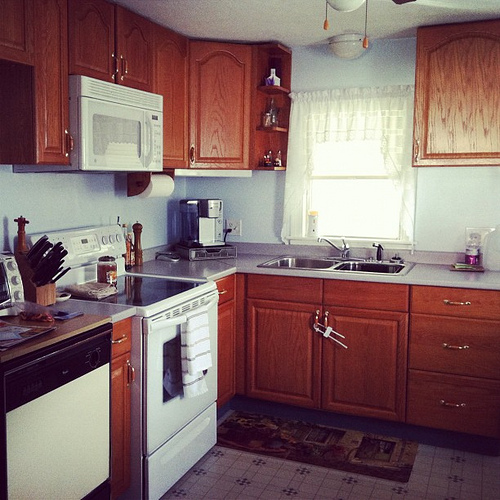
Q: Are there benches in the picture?
A: No, there are no benches.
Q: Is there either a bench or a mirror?
A: No, there are no benches or mirrors.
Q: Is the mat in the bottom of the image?
A: Yes, the mat is in the bottom of the image.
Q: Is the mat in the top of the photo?
A: No, the mat is in the bottom of the image.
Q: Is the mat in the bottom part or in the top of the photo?
A: The mat is in the bottom of the image.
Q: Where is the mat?
A: The mat is on the floor.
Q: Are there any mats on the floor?
A: Yes, there is a mat on the floor.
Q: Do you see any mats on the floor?
A: Yes, there is a mat on the floor.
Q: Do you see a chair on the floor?
A: No, there is a mat on the floor.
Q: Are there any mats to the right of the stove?
A: Yes, there is a mat to the right of the stove.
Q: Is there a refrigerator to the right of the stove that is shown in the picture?
A: No, there is a mat to the right of the stove.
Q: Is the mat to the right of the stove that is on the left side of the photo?
A: Yes, the mat is to the right of the stove.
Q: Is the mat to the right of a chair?
A: No, the mat is to the right of the stove.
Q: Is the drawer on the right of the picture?
A: Yes, the drawer is on the right of the image.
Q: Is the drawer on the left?
A: No, the drawer is on the right of the image.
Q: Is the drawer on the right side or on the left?
A: The drawer is on the right of the image.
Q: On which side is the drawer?
A: The drawer is on the right of the image.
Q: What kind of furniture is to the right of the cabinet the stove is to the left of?
A: The piece of furniture is a drawer.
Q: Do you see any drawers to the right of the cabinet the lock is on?
A: Yes, there is a drawer to the right of the cabinet.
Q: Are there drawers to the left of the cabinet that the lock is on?
A: No, the drawer is to the right of the cabinet.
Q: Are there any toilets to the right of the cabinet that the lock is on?
A: No, there is a drawer to the right of the cabinet.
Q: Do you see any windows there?
A: Yes, there are windows.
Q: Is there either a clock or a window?
A: Yes, there are windows.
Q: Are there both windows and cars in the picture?
A: No, there are windows but no cars.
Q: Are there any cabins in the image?
A: No, there are no cabins.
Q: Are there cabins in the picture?
A: No, there are no cabins.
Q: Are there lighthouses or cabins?
A: No, there are no cabins or lighthouses.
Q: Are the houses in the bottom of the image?
A: Yes, the houses are in the bottom of the image.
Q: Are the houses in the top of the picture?
A: No, the houses are in the bottom of the image.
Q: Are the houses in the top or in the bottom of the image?
A: The houses are in the bottom of the image.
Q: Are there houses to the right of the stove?
A: Yes, there are houses to the right of the stove.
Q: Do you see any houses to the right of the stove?
A: Yes, there are houses to the right of the stove.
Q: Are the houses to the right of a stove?
A: Yes, the houses are to the right of a stove.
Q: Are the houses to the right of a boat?
A: No, the houses are to the right of a stove.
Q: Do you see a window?
A: Yes, there are windows.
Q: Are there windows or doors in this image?
A: Yes, there are windows.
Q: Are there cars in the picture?
A: No, there are no cars.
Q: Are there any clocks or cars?
A: No, there are no cars or clocks.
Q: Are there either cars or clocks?
A: No, there are no cars or clocks.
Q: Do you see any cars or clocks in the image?
A: No, there are no cars or clocks.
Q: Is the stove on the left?
A: Yes, the stove is on the left of the image.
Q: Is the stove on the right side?
A: No, the stove is on the left of the image.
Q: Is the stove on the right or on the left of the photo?
A: The stove is on the left of the image.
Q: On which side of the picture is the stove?
A: The stove is on the left of the image.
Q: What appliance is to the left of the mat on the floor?
A: The appliance is a stove.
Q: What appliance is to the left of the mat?
A: The appliance is a stove.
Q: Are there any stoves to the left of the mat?
A: Yes, there is a stove to the left of the mat.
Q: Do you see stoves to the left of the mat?
A: Yes, there is a stove to the left of the mat.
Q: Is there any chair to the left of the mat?
A: No, there is a stove to the left of the mat.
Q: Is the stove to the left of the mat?
A: Yes, the stove is to the left of the mat.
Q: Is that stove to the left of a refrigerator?
A: No, the stove is to the left of the mat.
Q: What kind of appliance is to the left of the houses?
A: The appliance is a stove.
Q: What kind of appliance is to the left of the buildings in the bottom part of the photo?
A: The appliance is a stove.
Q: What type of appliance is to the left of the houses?
A: The appliance is a stove.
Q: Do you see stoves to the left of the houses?
A: Yes, there is a stove to the left of the houses.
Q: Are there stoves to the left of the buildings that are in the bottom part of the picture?
A: Yes, there is a stove to the left of the houses.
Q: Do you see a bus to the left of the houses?
A: No, there is a stove to the left of the houses.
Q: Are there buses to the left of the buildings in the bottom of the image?
A: No, there is a stove to the left of the houses.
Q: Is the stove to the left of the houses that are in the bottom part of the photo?
A: Yes, the stove is to the left of the houses.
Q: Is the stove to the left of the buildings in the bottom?
A: Yes, the stove is to the left of the houses.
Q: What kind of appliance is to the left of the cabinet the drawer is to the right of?
A: The appliance is a stove.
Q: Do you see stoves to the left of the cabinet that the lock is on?
A: Yes, there is a stove to the left of the cabinet.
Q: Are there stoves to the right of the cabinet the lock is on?
A: No, the stove is to the left of the cabinet.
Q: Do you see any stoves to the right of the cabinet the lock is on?
A: No, the stove is to the left of the cabinet.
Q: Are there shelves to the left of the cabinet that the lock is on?
A: No, there is a stove to the left of the cabinet.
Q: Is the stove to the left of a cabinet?
A: Yes, the stove is to the left of a cabinet.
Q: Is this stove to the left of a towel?
A: No, the stove is to the left of a cabinet.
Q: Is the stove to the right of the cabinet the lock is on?
A: No, the stove is to the left of the cabinet.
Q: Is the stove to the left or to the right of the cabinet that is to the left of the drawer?
A: The stove is to the left of the cabinet.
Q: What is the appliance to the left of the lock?
A: The appliance is a stove.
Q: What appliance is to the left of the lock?
A: The appliance is a stove.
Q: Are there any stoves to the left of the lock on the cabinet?
A: Yes, there is a stove to the left of the lock.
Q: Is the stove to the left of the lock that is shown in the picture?
A: Yes, the stove is to the left of the lock.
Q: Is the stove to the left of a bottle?
A: No, the stove is to the left of the lock.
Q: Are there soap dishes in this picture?
A: No, there are no soap dishes.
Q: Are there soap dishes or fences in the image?
A: No, there are no soap dishes or fences.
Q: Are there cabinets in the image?
A: Yes, there is a cabinet.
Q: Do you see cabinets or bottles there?
A: Yes, there is a cabinet.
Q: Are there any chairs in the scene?
A: No, there are no chairs.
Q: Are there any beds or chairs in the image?
A: No, there are no chairs or beds.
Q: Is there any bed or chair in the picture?
A: No, there are no chairs or beds.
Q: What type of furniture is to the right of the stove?
A: The piece of furniture is a cabinet.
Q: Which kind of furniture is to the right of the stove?
A: The piece of furniture is a cabinet.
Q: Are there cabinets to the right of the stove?
A: Yes, there is a cabinet to the right of the stove.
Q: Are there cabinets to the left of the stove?
A: No, the cabinet is to the right of the stove.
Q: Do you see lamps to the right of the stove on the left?
A: No, there is a cabinet to the right of the stove.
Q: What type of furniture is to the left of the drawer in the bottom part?
A: The piece of furniture is a cabinet.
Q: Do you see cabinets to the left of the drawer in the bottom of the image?
A: Yes, there is a cabinet to the left of the drawer.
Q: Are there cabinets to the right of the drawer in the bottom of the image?
A: No, the cabinet is to the left of the drawer.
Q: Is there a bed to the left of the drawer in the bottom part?
A: No, there is a cabinet to the left of the drawer.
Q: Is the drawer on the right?
A: Yes, the drawer is on the right of the image.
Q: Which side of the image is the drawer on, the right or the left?
A: The drawer is on the right of the image.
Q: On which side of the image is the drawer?
A: The drawer is on the right of the image.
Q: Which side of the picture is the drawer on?
A: The drawer is on the right of the image.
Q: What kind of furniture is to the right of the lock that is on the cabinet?
A: The piece of furniture is a drawer.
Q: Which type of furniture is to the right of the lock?
A: The piece of furniture is a drawer.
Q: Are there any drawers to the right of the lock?
A: Yes, there is a drawer to the right of the lock.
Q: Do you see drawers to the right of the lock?
A: Yes, there is a drawer to the right of the lock.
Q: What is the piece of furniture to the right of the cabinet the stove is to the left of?
A: The piece of furniture is a drawer.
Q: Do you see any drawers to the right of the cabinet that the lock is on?
A: Yes, there is a drawer to the right of the cabinet.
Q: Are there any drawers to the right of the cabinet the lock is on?
A: Yes, there is a drawer to the right of the cabinet.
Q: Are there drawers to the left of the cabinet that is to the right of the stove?
A: No, the drawer is to the right of the cabinet.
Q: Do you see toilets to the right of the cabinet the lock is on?
A: No, there is a drawer to the right of the cabinet.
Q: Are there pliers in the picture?
A: No, there are no pliers.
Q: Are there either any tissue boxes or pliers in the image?
A: No, there are no pliers or tissue boxes.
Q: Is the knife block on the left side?
A: Yes, the knife block is on the left of the image.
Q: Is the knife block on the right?
A: No, the knife block is on the left of the image.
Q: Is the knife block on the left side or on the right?
A: The knife block is on the left of the image.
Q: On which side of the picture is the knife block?
A: The knife block is on the left of the image.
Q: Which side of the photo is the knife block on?
A: The knife block is on the left of the image.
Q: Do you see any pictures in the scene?
A: No, there are no pictures.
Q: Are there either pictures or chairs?
A: No, there are no pictures or chairs.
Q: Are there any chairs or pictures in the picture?
A: No, there are no pictures or chairs.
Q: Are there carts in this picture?
A: No, there are no carts.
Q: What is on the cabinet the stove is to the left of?
A: The lock is on the cabinet.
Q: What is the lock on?
A: The lock is on the cabinet.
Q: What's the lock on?
A: The lock is on the cabinet.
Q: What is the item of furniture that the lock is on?
A: The piece of furniture is a cabinet.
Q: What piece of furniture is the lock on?
A: The lock is on the cabinet.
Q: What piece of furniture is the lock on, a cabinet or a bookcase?
A: The lock is on a cabinet.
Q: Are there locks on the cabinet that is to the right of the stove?
A: Yes, there is a lock on the cabinet.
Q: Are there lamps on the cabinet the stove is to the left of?
A: No, there is a lock on the cabinet.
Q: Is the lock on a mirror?
A: No, the lock is on the cabinet.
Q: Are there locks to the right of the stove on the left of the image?
A: Yes, there is a lock to the right of the stove.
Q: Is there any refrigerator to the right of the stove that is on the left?
A: No, there is a lock to the right of the stove.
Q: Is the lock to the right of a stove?
A: Yes, the lock is to the right of a stove.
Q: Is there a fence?
A: No, there are no fences.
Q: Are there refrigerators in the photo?
A: No, there are no refrigerators.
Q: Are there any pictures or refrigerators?
A: No, there are no refrigerators or pictures.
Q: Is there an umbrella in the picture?
A: No, there are no umbrellas.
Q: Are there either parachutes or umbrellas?
A: No, there are no umbrellas or parachutes.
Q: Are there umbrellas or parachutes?
A: No, there are no umbrellas or parachutes.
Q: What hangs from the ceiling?
A: The cords hang from the ceiling.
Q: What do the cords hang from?
A: The cords hang from the ceiling.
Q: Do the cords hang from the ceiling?
A: Yes, the cords hang from the ceiling.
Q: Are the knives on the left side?
A: Yes, the knives are on the left of the image.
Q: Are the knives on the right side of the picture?
A: No, the knives are on the left of the image.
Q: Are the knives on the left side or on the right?
A: The knives are on the left of the image.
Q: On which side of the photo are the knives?
A: The knives are on the left of the image.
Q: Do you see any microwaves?
A: Yes, there is a microwave.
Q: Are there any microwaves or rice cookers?
A: Yes, there is a microwave.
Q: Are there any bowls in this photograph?
A: No, there are no bowls.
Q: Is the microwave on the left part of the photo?
A: Yes, the microwave is on the left of the image.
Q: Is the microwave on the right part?
A: No, the microwave is on the left of the image.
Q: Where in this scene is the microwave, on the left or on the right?
A: The microwave is on the left of the image.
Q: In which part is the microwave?
A: The microwave is on the left of the image.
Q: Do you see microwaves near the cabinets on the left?
A: Yes, there is a microwave near the cabinets.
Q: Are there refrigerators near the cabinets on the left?
A: No, there is a microwave near the cabinets.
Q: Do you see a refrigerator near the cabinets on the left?
A: No, there is a microwave near the cabinets.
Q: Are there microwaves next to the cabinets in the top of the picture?
A: Yes, there is a microwave next to the cabinets.